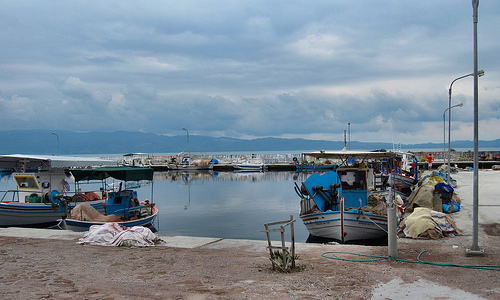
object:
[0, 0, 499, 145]
sky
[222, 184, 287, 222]
water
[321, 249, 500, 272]
hose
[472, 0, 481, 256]
pole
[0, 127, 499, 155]
mountain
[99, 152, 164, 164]
green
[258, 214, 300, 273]
strick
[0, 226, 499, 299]
ground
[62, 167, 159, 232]
boat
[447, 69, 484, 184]
lamp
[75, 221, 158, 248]
rag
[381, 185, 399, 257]
contraption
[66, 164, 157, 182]
tarp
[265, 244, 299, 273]
plant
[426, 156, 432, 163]
shirt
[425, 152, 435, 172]
person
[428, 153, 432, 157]
hair